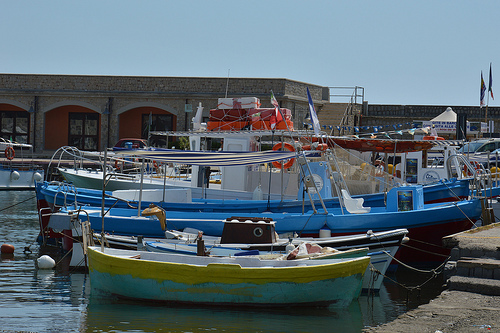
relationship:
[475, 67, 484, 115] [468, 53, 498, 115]
poles has flags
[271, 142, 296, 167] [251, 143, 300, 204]
life preserver hanging on wall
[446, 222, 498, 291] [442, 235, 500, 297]
walkway has stair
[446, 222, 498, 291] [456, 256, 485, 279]
walkway has stair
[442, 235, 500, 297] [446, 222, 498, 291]
stair on walkway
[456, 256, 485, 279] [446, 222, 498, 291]
stair on walkway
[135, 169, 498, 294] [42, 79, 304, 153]
stairs leading to building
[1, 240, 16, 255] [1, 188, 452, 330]
buoy floating on water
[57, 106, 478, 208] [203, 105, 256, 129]
boat with cone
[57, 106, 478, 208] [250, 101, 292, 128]
boat with cone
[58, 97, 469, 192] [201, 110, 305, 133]
boat with orange cones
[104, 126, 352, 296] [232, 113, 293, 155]
boat with cone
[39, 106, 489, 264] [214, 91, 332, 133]
boat with cones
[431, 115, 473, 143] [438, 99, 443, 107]
boat with cones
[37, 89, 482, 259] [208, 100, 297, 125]
boat with cones